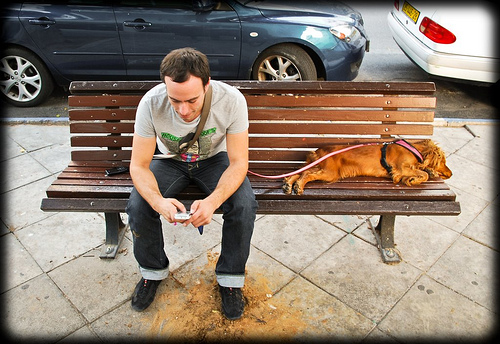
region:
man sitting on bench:
[129, 49, 258, 318]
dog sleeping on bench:
[276, 132, 453, 204]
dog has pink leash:
[246, 132, 458, 194]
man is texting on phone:
[162, 194, 208, 227]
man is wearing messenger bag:
[113, 80, 222, 160]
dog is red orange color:
[278, 124, 460, 191]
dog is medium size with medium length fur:
[278, 136, 454, 192]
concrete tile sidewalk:
[6, 114, 499, 331]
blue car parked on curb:
[3, 3, 377, 110]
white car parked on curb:
[386, 1, 499, 98]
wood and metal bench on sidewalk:
[40, 79, 465, 266]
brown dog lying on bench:
[278, 130, 460, 198]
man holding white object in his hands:
[161, 198, 211, 234]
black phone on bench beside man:
[97, 139, 169, 209]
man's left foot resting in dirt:
[176, 255, 302, 342]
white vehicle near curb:
[382, 0, 499, 149]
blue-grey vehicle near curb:
[2, 0, 381, 152]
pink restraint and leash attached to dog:
[238, 133, 428, 190]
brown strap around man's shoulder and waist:
[137, 79, 227, 166]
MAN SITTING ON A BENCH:
[56, 41, 281, 317]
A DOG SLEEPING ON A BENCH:
[257, 76, 479, 233]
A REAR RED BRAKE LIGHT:
[419, 6, 461, 56]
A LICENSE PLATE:
[391, 3, 430, 26]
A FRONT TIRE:
[253, 36, 334, 89]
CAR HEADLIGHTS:
[322, 4, 363, 60]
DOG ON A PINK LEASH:
[253, 108, 462, 200]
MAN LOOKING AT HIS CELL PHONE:
[124, 41, 270, 328]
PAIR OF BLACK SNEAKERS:
[125, 272, 264, 322]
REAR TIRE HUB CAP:
[1, 37, 50, 117]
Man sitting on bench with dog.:
[121, 47, 275, 317]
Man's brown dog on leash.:
[281, 136, 454, 201]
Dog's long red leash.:
[261, 138, 425, 176]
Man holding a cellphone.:
[163, 198, 206, 238]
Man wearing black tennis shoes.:
[128, 272, 253, 322]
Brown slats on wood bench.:
[38, 74, 125, 219]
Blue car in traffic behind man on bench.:
[2, 2, 363, 107]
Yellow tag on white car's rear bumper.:
[400, 2, 424, 27]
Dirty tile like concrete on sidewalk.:
[306, 243, 498, 333]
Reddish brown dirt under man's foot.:
[177, 265, 302, 339]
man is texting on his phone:
[137, 50, 307, 335]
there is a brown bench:
[73, 79, 464, 225]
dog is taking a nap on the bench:
[290, 110, 460, 196]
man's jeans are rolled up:
[115, 247, 272, 339]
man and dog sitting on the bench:
[90, 37, 470, 342]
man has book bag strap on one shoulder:
[116, 87, 260, 196]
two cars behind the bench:
[4, 2, 499, 119]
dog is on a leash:
[270, 127, 467, 202]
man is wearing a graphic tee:
[153, 120, 255, 169]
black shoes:
[115, 266, 275, 340]